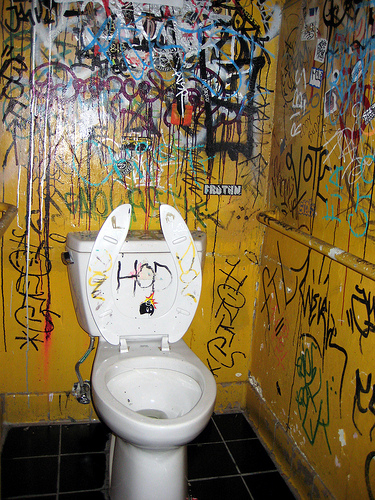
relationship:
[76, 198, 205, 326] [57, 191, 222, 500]
graffiti on toilet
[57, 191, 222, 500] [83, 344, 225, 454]
toilet has bowl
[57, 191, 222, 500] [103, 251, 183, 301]
toilet says hod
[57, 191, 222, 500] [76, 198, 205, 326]
toilet has graffiti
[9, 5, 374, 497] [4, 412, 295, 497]
bathroom has black tile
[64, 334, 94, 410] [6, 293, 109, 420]
pipeline in wall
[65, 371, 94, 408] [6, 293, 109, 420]
control in wall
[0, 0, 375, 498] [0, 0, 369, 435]
wall covered in graffiti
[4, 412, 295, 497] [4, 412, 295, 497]
tile on floor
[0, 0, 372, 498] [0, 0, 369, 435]
graffiti on wall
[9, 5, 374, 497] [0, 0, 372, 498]
bathroom with graffiti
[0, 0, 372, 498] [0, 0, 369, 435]
graffiti on walls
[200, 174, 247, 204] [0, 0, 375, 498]
sticker on wall